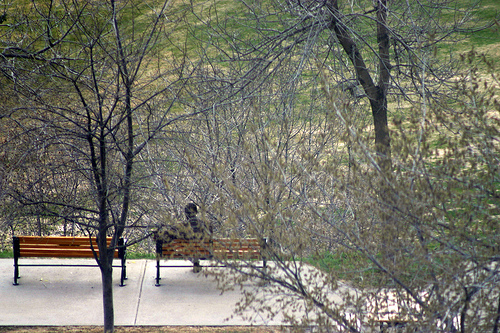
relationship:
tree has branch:
[57, 135, 172, 325] [132, 56, 293, 148]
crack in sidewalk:
[132, 259, 149, 329] [4, 250, 403, 333]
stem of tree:
[85, 218, 146, 317] [57, 135, 172, 325]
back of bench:
[17, 223, 122, 269] [18, 223, 136, 290]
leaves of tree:
[119, 20, 191, 100] [57, 135, 172, 325]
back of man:
[158, 225, 205, 258] [150, 176, 227, 270]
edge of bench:
[105, 245, 128, 273] [18, 223, 136, 290]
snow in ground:
[147, 304, 175, 331] [138, 291, 191, 324]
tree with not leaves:
[57, 135, 172, 325] [119, 20, 191, 100]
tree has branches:
[57, 135, 172, 325] [129, 69, 223, 156]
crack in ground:
[128, 276, 167, 332] [138, 291, 191, 324]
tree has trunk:
[57, 135, 172, 325] [85, 218, 146, 317]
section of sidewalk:
[124, 295, 222, 322] [4, 250, 403, 333]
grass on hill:
[210, 22, 299, 90] [185, 48, 299, 108]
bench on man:
[18, 223, 136, 290] [150, 197, 219, 276]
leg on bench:
[90, 239, 142, 298] [18, 223, 136, 290]